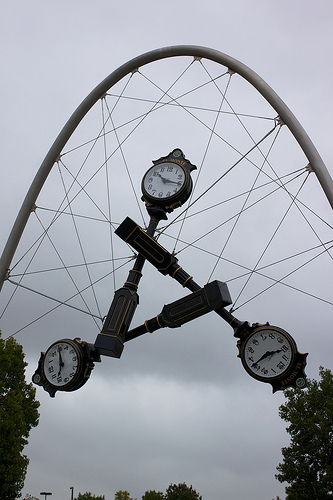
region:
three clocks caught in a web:
[27, 143, 331, 396]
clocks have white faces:
[245, 328, 295, 377]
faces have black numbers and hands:
[41, 341, 79, 390]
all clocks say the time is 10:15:
[139, 159, 198, 199]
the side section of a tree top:
[271, 367, 331, 499]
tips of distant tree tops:
[78, 483, 200, 498]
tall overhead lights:
[37, 483, 75, 499]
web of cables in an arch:
[1, 41, 331, 343]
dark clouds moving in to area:
[33, 224, 332, 409]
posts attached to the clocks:
[94, 207, 237, 353]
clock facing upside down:
[222, 313, 312, 396]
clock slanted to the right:
[141, 135, 207, 215]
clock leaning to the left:
[21, 316, 104, 408]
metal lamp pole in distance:
[59, 477, 80, 492]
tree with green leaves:
[278, 398, 324, 458]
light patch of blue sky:
[134, 384, 166, 401]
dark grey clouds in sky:
[172, 339, 207, 370]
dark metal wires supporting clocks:
[227, 179, 284, 269]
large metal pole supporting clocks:
[61, 93, 126, 119]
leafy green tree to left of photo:
[6, 371, 27, 436]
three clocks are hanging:
[49, 124, 313, 423]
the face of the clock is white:
[218, 313, 292, 379]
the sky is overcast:
[103, 371, 274, 489]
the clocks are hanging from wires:
[30, 128, 313, 391]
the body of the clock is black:
[96, 209, 166, 355]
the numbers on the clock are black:
[127, 152, 187, 198]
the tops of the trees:
[55, 481, 214, 498]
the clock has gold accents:
[93, 263, 164, 353]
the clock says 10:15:
[106, 144, 214, 206]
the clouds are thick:
[115, 355, 239, 472]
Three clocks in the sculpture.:
[34, 144, 312, 402]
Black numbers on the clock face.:
[237, 327, 292, 377]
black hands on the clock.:
[47, 344, 79, 380]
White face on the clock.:
[143, 163, 186, 197]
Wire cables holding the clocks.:
[2, 56, 331, 321]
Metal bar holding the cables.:
[2, 43, 331, 288]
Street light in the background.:
[65, 484, 76, 497]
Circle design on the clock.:
[293, 376, 305, 387]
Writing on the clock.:
[274, 356, 305, 388]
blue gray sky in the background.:
[0, 3, 330, 497]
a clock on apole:
[83, 115, 198, 240]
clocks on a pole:
[10, 145, 331, 450]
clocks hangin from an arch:
[18, 57, 327, 382]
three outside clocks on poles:
[26, 149, 282, 435]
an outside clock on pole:
[72, 129, 286, 397]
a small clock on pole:
[81, 139, 239, 331]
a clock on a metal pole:
[121, 72, 245, 303]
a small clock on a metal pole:
[189, 304, 324, 424]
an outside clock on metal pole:
[180, 261, 328, 444]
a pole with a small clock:
[185, 260, 325, 436]